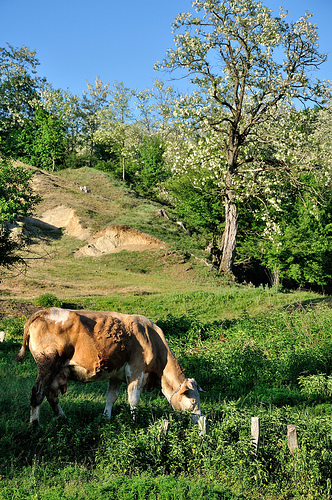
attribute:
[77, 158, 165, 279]
hill — steep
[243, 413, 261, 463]
post — brown, wooden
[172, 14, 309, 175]
tree — large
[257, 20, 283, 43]
buds — white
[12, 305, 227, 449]
cow — brown, tan, eating, skinny, grazing, white, large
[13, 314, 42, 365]
tail — short, brown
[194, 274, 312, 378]
field — green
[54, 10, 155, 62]
sky — blue, clear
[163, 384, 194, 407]
rope — brown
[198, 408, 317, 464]
fence — old, broken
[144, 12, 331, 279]
trees — tall